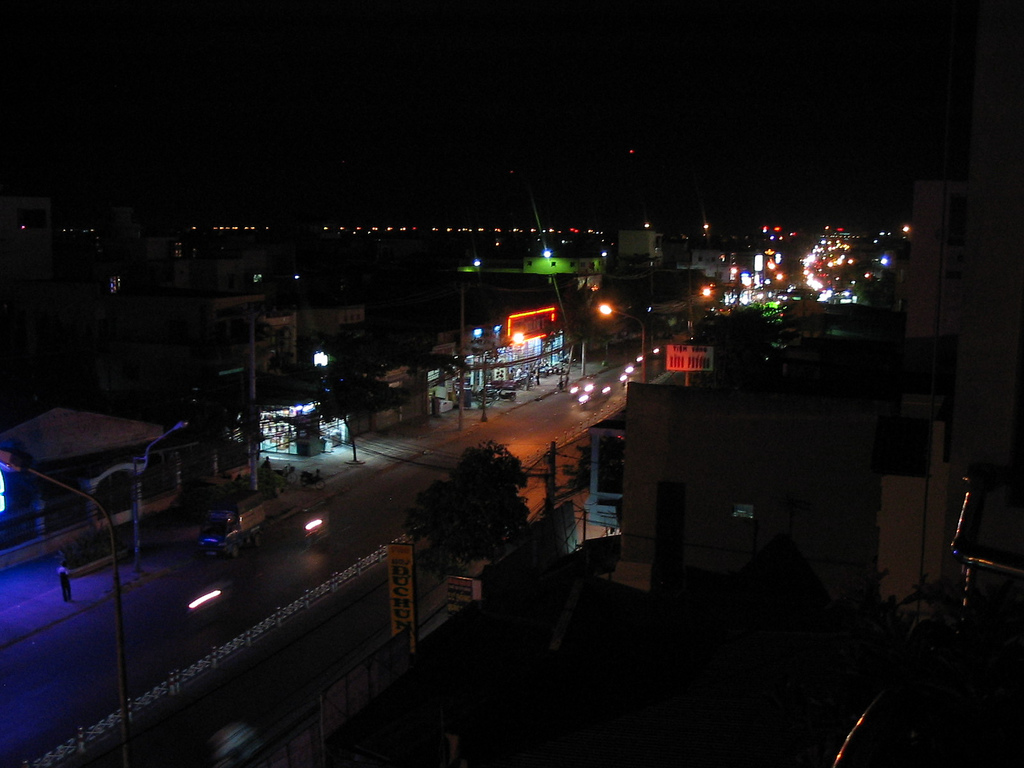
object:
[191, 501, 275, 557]
truck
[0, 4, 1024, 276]
sky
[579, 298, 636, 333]
lights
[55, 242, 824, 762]
road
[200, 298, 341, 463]
set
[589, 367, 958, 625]
buildings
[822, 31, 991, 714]
right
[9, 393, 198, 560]
buildings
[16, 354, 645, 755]
street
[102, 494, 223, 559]
curb